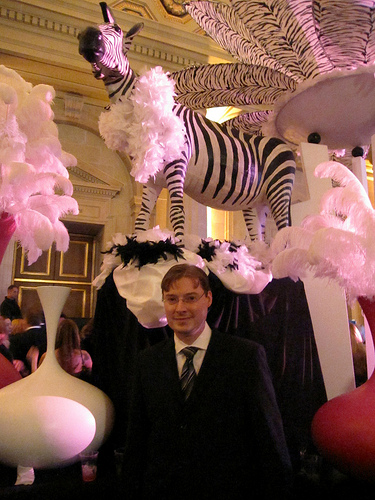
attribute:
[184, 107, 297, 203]
stripes — black, white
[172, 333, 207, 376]
shirt — white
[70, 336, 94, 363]
straps — thin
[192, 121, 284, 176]
stripe — white, black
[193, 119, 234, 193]
white stripes — black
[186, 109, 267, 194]
stripes — white, black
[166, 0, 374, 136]
feathers — black white and striped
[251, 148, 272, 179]
stripes — black, white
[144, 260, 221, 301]
hair — long, brown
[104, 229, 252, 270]
feathers — black, white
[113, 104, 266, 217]
stripes — black, white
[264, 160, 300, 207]
stripes — white, black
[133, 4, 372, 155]
plumes — white, black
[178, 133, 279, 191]
stripes — black, white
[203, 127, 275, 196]
stripes — white, black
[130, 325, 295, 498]
suit — black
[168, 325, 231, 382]
shirt — white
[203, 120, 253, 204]
stripes — black, white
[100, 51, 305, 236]
zebra statue — large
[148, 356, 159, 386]
suit — three piece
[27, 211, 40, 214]
feather — white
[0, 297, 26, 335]
sweater — black